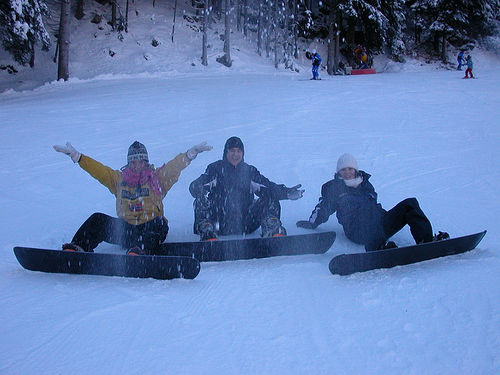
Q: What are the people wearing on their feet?
A: Snowboards.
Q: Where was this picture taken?
A: Slopes.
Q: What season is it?
A: Winter.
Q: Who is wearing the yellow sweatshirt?
A: Girl on the left.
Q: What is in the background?
A: Trees.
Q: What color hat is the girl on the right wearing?
A: White.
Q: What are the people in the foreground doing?
A: Sitting.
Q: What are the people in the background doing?
A: Snowboarding.